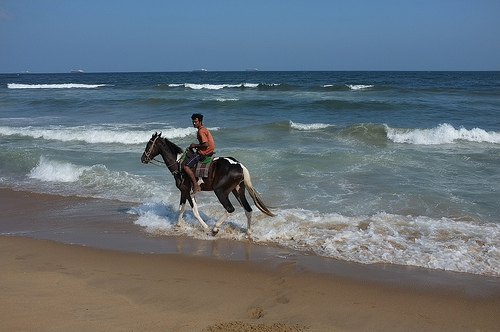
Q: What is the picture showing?
A: It is showing an ocean.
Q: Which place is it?
A: It is an ocean.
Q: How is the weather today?
A: It is clear.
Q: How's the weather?
A: It is clear.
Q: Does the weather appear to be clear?
A: Yes, it is clear.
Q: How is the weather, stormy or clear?
A: It is clear.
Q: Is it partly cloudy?
A: No, it is clear.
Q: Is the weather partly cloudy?
A: No, it is clear.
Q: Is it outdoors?
A: Yes, it is outdoors.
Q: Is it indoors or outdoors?
A: It is outdoors.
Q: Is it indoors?
A: No, it is outdoors.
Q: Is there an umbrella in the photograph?
A: No, there are no umbrellas.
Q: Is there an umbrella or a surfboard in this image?
A: No, there are no umbrellas or surfboards.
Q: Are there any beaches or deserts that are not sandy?
A: No, there is a beach but it is sandy.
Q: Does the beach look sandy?
A: Yes, the beach is sandy.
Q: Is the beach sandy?
A: Yes, the beach is sandy.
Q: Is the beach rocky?
A: No, the beach is sandy.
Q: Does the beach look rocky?
A: No, the beach is sandy.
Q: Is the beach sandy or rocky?
A: The beach is sandy.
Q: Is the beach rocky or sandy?
A: The beach is sandy.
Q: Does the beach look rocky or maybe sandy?
A: The beach is sandy.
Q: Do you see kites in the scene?
A: No, there are no kites.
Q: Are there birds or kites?
A: No, there are no kites or birds.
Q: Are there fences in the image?
A: No, there are no fences.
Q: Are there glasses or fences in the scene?
A: No, there are no fences or glasses.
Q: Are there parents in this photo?
A: No, there are no parents.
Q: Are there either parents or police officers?
A: No, there are no parents or police officers.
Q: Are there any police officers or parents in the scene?
A: No, there are no parents or police officers.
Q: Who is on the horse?
A: The boy is on the horse.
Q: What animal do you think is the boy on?
A: The boy is on the horse.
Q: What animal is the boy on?
A: The boy is on the horse.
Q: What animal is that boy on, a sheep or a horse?
A: The boy is on a horse.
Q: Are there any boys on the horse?
A: Yes, there is a boy on the horse.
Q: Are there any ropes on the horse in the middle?
A: No, there is a boy on the horse.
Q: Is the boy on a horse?
A: Yes, the boy is on a horse.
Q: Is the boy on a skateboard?
A: No, the boy is on a horse.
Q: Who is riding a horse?
A: The boy is riding a horse.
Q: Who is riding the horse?
A: The boy is riding a horse.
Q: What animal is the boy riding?
A: The boy is riding a horse.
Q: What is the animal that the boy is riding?
A: The animal is a horse.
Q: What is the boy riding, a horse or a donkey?
A: The boy is riding a horse.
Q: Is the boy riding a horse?
A: Yes, the boy is riding a horse.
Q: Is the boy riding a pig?
A: No, the boy is riding a horse.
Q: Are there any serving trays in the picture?
A: No, there are no serving trays.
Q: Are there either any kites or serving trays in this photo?
A: No, there are no serving trays or kites.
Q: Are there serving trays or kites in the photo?
A: No, there are no serving trays or kites.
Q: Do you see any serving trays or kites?
A: No, there are no serving trays or kites.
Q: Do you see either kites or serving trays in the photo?
A: No, there are no serving trays or kites.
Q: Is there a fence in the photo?
A: No, there are no fences.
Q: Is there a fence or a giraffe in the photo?
A: No, there are no fences or giraffes.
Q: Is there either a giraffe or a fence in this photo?
A: No, there are no fences or giraffes.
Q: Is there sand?
A: Yes, there is sand.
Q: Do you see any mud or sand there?
A: Yes, there is sand.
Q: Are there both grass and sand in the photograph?
A: No, there is sand but no grass.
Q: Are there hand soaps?
A: No, there are no hand soaps.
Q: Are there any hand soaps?
A: No, there are no hand soaps.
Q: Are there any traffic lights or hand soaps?
A: No, there are no hand soaps or traffic lights.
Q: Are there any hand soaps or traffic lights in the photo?
A: No, there are no hand soaps or traffic lights.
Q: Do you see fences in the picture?
A: No, there are no fences.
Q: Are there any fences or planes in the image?
A: No, there are no fences or planes.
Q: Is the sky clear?
A: Yes, the sky is clear.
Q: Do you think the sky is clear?
A: Yes, the sky is clear.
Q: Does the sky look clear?
A: Yes, the sky is clear.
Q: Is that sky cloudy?
A: No, the sky is clear.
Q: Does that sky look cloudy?
A: No, the sky is clear.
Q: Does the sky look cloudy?
A: No, the sky is clear.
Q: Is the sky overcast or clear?
A: The sky is clear.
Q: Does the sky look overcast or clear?
A: The sky is clear.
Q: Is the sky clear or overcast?
A: The sky is clear.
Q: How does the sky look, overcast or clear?
A: The sky is clear.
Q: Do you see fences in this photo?
A: No, there are no fences.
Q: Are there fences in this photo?
A: No, there are no fences.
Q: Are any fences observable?
A: No, there are no fences.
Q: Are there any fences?
A: No, there are no fences.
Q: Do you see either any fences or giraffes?
A: No, there are no fences or giraffes.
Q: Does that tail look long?
A: Yes, the tail is long.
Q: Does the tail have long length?
A: Yes, the tail is long.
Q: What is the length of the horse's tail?
A: The tail is long.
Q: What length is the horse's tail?
A: The tail is long.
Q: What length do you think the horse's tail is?
A: The tail is long.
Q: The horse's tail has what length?
A: The tail is long.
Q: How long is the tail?
A: The tail is long.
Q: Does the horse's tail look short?
A: No, the tail is long.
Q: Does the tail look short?
A: No, the tail is long.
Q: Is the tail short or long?
A: The tail is long.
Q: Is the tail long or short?
A: The tail is long.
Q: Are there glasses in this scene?
A: No, there are no glasses.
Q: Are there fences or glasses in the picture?
A: No, there are no glasses or fences.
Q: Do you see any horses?
A: Yes, there is a horse.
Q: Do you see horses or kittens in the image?
A: Yes, there is a horse.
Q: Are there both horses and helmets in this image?
A: No, there is a horse but no helmets.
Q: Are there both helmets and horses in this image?
A: No, there is a horse but no helmets.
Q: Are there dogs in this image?
A: No, there are no dogs.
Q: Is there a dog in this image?
A: No, there are no dogs.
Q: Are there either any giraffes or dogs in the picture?
A: No, there are no dogs or giraffes.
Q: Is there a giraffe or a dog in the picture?
A: No, there are no dogs or giraffes.